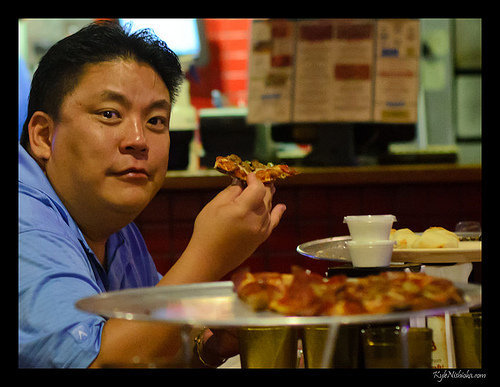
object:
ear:
[28, 111, 53, 160]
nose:
[119, 115, 151, 154]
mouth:
[112, 166, 154, 184]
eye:
[147, 116, 169, 126]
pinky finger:
[268, 202, 288, 233]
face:
[51, 59, 173, 210]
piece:
[212, 154, 299, 184]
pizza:
[230, 266, 463, 318]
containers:
[341, 213, 396, 241]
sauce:
[344, 238, 396, 268]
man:
[19, 20, 287, 368]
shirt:
[20, 148, 167, 368]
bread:
[409, 226, 459, 250]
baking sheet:
[295, 230, 481, 268]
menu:
[247, 19, 420, 123]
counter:
[133, 163, 481, 277]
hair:
[19, 18, 185, 149]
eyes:
[96, 110, 124, 120]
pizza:
[213, 154, 296, 184]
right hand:
[195, 169, 286, 271]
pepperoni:
[282, 285, 312, 306]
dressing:
[343, 214, 398, 241]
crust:
[228, 174, 286, 184]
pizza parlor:
[19, 18, 482, 368]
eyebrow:
[95, 88, 131, 109]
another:
[346, 240, 395, 266]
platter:
[73, 274, 481, 328]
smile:
[108, 166, 154, 185]